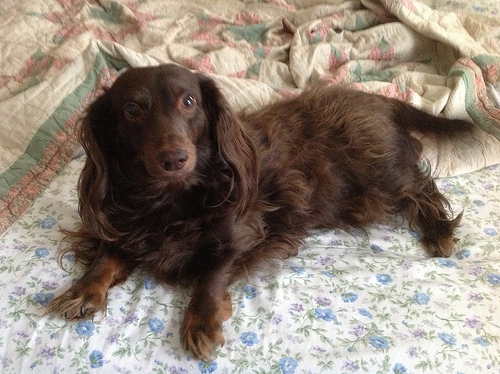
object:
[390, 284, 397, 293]
leaves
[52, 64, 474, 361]
dog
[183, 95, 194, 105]
eye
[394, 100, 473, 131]
tail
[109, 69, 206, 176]
face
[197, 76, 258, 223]
ear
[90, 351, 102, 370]
flower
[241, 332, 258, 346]
flower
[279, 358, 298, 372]
flower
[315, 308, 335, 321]
flower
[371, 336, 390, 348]
flower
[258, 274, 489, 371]
sheet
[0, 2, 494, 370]
bed